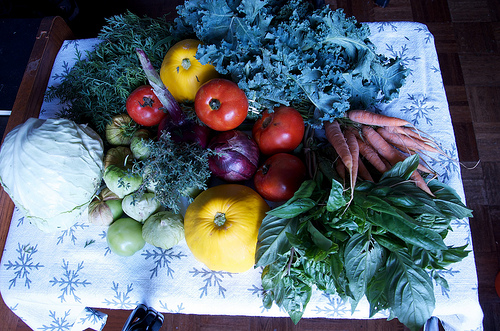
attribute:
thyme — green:
[53, 11, 176, 124]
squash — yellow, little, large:
[154, 39, 213, 93]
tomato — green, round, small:
[104, 213, 155, 260]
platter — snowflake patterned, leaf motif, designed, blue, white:
[9, 17, 472, 329]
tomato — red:
[123, 85, 164, 124]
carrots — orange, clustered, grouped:
[256, 11, 444, 210]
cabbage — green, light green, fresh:
[3, 114, 105, 228]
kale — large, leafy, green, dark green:
[179, 2, 406, 119]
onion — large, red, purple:
[205, 131, 258, 180]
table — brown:
[0, 12, 485, 330]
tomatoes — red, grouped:
[125, 81, 308, 203]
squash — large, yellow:
[188, 186, 274, 276]